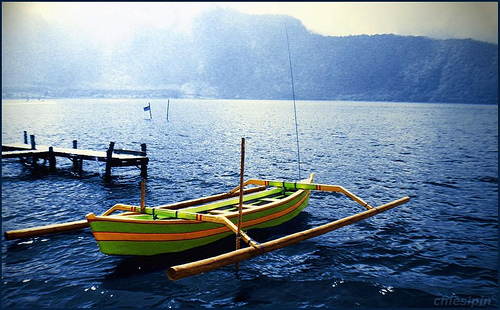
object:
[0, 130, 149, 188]
boat dock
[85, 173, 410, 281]
boat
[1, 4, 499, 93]
background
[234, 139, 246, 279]
pole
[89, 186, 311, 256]
stripe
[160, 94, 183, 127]
pole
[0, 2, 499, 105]
hills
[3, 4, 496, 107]
distance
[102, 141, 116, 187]
post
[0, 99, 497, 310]
lake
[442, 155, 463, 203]
waves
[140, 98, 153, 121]
bouy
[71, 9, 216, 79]
fog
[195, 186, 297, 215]
boards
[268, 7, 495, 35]
sky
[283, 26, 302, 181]
wire